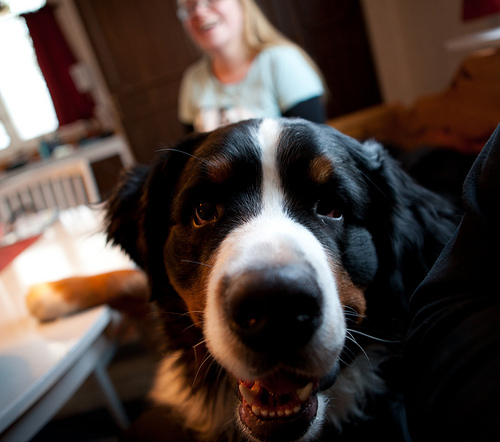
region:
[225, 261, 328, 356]
one rounded black dog nose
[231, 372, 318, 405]
two pointy canine teeth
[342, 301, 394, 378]
left side dog whiskers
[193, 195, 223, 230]
one rounded dark dog eye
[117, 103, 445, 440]
one black and white dog head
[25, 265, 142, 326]
one animal paw resting on shiny white table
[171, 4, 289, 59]
woman with long straight blonde hair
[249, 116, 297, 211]
white stripe on dog forehead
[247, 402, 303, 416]
several little front dog teeth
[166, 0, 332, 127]
woman wearing black and white shirt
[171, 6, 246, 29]
The lady is wearing glasses.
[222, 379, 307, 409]
The dog teeth in his mouth.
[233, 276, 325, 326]
The dog has a black nose.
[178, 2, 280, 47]
The lady is smiling.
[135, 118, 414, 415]
The dog is black and white.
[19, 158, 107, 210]
A white chair by the table.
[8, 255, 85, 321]
A paw on the table.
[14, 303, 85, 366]
The table is white.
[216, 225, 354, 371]
The dog face is partially white.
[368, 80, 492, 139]
A chair in the background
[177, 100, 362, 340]
a white line on dog's face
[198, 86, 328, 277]
a white line on dog's face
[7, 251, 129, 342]
dog's paw on the table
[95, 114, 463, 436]
the face of a happy dog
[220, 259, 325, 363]
the nose of a dog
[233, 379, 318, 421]
the teeth in a dog's mouth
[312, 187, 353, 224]
the eye of a dog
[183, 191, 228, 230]
the eye of a dog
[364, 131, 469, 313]
the ear of a dog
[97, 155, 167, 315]
the ear of a dog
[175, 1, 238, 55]
a face of a woman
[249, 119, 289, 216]
a stripe of fur on a dog's head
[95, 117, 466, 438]
the head of a dog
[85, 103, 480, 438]
an animal looking at the camera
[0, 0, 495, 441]
a scene inside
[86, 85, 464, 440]
a white and black dog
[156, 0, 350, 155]
a woman in the background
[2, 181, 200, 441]
a white table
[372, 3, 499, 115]
a white wall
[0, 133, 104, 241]
a white chair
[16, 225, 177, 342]
a paw on the table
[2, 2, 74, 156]
a window in the background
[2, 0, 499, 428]
a scene in the living room